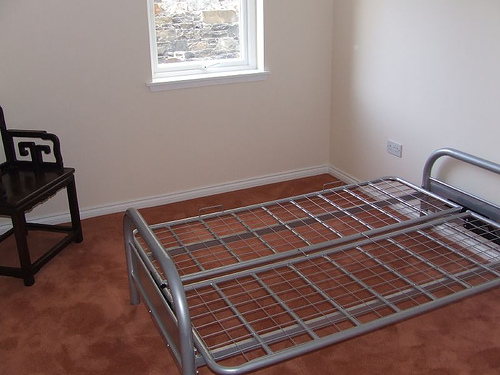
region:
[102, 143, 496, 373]
silver metal futon fram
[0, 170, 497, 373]
rust coloured carpet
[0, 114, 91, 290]
black wooden chair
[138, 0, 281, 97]
distorted glass window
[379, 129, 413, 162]
horizontal electrical wall outlet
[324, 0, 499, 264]
creme coloured painted wall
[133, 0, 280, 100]
white painted wooden window frame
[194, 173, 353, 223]
metal futon frame handles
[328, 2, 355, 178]
shadow in the corner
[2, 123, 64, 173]
intricately carved wooden arm rest of chair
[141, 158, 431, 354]
an empty bed frame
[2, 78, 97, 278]
the chair against the wall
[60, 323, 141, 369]
the brown carpet in the room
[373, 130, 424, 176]
an electric out let on the wall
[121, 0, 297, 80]
a window that appears to be blocked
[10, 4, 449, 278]
an empty room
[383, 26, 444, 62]
the nice white wall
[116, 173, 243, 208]
the modling on the edges of the ground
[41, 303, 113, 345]
the carpet that is brown on the floor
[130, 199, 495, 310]
a grey or silver bed frame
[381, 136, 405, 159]
Outlet on the wall.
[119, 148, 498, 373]
Metal bed frame in room.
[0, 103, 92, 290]
Wooden chair in the corner.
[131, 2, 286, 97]
Window on the wall.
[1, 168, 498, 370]
Rust colored carpet in the room.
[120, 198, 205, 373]
Metal footboard on bed.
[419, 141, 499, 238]
Metal headboard on the bed.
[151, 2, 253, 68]
Brick wall seen through window.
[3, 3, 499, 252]
Off white wall in the room.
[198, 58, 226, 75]
Handle on the window.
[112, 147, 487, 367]
Gray metal bedframe laying on the ground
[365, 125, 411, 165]
White outlet in the wall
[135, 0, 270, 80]
Window in a white wall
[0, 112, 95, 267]
Small black chair leaning against the wall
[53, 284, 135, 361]
Orange floor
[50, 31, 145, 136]
White wall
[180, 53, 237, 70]
White lock on the window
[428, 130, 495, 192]
Metal headboard of a bed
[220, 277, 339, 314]
Interlocking metal frame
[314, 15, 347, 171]
Corner of the white wall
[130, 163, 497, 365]
An empty bed frame.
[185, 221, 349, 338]
Bars on the bed frame.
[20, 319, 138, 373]
An orange carpet.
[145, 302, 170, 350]
bolts on the bed frame.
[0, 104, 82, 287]
A wooden chair in the corner.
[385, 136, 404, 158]
An electrical wall socket.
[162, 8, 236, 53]
A stone wall outside.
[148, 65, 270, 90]
A white window seal.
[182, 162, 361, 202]
A white base board.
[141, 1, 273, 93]
A window with no screen.